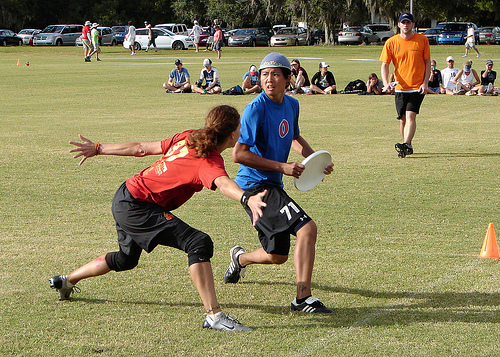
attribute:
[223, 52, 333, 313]
man — young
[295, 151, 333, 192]
frisbee — white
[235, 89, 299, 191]
shirt — blue, red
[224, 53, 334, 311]
frisbee player — man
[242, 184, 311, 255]
shorts — black, white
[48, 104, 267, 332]
woman — blocking, frisbee player, young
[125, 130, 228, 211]
shirt — red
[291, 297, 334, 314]
shoe — black, white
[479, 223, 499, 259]
cone — orange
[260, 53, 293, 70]
hat — blue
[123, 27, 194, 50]
car — white, parked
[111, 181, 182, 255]
shorts — black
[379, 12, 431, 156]
man — walking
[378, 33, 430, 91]
shirt — orange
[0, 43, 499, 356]
grass — green, brown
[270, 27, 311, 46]
car — distant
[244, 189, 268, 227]
hand — stretched out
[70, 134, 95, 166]
hand — stretched out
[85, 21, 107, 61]
person — distant, walking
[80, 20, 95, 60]
person — distant, walking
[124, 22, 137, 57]
person — distant, walking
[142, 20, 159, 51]
person — distant, walking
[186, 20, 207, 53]
person — walking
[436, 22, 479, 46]
car — parked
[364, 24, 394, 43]
car — parked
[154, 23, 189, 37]
car — parked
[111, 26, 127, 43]
car — parked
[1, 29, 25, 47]
car — parked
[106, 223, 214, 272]
knee pads — black